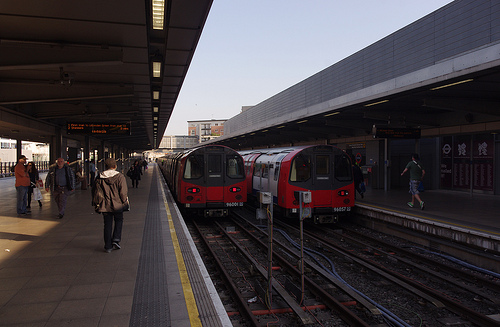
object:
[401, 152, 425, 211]
man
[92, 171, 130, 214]
gray jacket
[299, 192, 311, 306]
stand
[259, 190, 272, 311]
stand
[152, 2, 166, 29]
light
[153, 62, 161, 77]
light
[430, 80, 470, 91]
light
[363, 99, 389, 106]
light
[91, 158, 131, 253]
man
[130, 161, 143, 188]
passenger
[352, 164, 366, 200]
passenger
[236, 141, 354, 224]
train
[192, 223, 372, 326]
track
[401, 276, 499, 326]
track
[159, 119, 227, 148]
building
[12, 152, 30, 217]
man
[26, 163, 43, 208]
woman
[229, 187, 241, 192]
light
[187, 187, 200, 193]
light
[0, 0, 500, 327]
station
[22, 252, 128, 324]
floor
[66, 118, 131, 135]
sign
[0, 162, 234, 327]
platform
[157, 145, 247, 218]
passenger train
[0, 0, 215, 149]
awning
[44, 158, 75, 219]
man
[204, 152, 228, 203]
door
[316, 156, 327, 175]
window